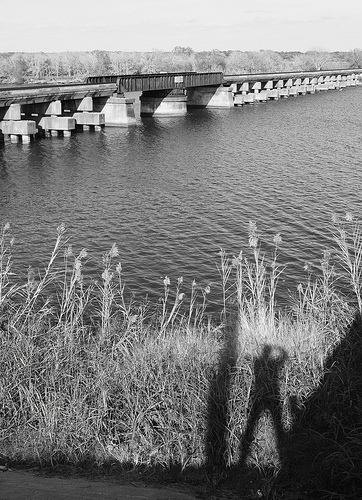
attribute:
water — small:
[1, 95, 361, 314]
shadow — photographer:
[242, 341, 288, 464]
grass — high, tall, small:
[0, 215, 350, 474]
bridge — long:
[0, 67, 350, 142]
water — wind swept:
[0, 87, 351, 324]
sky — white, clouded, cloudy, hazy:
[0, 2, 349, 53]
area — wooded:
[2, 51, 349, 85]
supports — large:
[5, 103, 81, 140]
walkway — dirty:
[2, 465, 227, 496]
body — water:
[0, 86, 347, 328]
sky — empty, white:
[0, 1, 346, 60]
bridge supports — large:
[102, 73, 240, 128]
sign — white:
[168, 66, 187, 88]